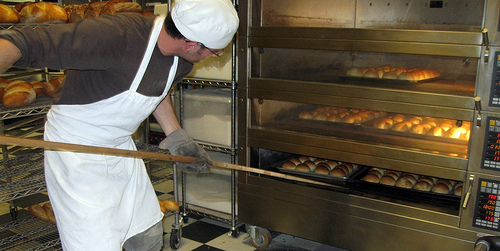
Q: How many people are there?
A: One.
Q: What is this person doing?
A: Cooking.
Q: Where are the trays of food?
A: In the oven.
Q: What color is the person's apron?
A: White.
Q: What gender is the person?
A: Male.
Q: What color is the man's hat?
A: White.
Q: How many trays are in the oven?
A: Five.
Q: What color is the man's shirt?
A: Black.